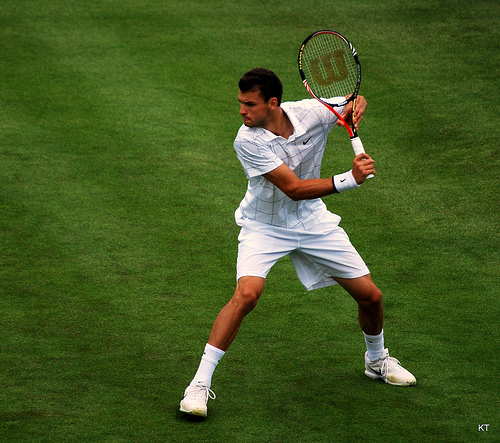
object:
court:
[0, 0, 499, 442]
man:
[177, 66, 419, 418]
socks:
[195, 340, 229, 375]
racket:
[295, 32, 376, 179]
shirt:
[232, 97, 348, 228]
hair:
[238, 68, 283, 107]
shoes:
[365, 351, 417, 387]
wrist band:
[331, 167, 366, 194]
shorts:
[234, 226, 368, 291]